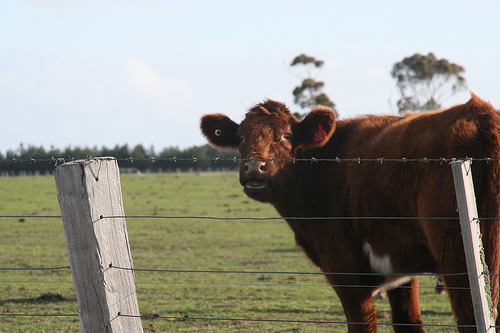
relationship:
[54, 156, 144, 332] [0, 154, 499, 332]
post part of fence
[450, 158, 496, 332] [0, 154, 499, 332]
post part of fence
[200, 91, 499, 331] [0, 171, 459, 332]
cow inside of field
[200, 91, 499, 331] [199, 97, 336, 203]
cow has head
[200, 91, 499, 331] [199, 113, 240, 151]
cow has ear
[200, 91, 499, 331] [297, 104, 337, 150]
cow has ear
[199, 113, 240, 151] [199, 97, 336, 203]
ear sticking out of head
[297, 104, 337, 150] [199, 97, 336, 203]
ear sticking out of head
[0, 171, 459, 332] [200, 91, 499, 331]
field for cow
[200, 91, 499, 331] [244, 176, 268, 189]
cow has mouth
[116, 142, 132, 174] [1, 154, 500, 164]
tree inside of wire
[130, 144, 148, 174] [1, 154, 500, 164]
tree inside of wire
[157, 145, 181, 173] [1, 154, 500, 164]
tree inside of wire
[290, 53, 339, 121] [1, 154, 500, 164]
tree inside of wire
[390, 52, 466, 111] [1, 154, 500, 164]
tree inside of wire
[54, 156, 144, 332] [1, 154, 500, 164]
post in between wire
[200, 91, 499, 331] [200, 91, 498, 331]
cow has fur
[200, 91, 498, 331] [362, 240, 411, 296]
fur has patch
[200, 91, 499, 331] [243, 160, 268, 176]
cow has nose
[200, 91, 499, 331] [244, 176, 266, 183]
cow has lip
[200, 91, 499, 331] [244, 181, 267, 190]
cow has lip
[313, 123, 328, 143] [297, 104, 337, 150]
tag inside of ear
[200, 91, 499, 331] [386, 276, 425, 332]
cow has leg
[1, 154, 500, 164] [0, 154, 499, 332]
wire at top of fence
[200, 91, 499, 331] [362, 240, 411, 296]
cow has patch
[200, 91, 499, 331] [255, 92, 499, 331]
cow has side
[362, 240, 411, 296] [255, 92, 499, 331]
patch on side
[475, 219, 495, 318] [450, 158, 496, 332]
moss growing on post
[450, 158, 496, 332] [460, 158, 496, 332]
post has side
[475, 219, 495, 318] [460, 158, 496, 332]
moss growing on side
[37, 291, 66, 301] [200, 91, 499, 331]
pile from cow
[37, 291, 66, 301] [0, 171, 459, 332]
pile inside of field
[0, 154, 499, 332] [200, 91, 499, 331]
fence next to cow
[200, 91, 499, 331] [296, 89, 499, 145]
cow has back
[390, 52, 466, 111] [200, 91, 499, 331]
tree behind cow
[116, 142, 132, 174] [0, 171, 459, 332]
tree next to field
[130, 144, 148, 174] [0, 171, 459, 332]
tree next to field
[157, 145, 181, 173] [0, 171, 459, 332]
tree next to field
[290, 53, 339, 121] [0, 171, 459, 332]
tree next to field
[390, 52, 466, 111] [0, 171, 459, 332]
tree next to field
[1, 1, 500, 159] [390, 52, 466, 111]
sky above tree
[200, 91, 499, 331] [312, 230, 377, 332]
cow has leg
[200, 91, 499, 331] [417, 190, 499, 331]
cow has leg